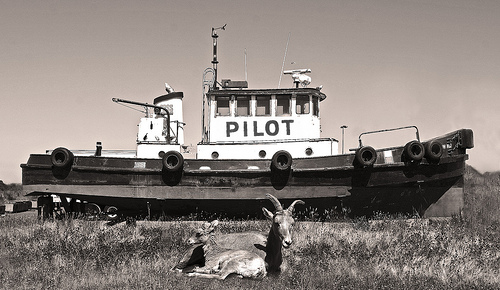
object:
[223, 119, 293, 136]
lettering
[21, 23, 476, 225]
ship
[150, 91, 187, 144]
stack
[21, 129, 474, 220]
hull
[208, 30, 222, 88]
pole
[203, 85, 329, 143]
structure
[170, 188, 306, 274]
goat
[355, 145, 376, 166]
tire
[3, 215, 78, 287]
grass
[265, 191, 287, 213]
horn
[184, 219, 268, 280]
baby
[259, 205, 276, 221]
ear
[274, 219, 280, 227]
eye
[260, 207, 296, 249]
head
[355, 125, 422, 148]
rail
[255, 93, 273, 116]
window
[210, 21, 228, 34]
vane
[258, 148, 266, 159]
porthole